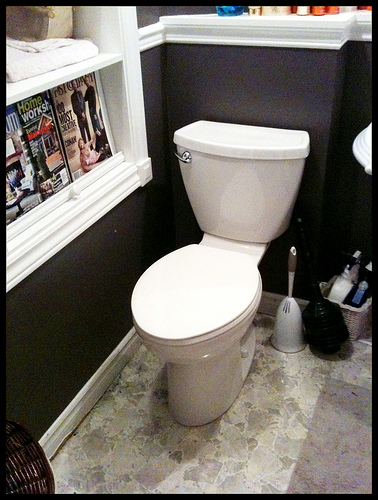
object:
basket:
[5, 420, 54, 494]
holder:
[268, 248, 307, 354]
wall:
[4, 4, 166, 470]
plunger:
[290, 210, 349, 357]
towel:
[5, 37, 98, 82]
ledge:
[157, 12, 352, 51]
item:
[213, 4, 242, 16]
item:
[246, 5, 261, 17]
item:
[295, 5, 310, 14]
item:
[275, 4, 291, 17]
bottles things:
[311, 6, 325, 19]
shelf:
[158, 11, 355, 50]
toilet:
[129, 118, 309, 430]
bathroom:
[5, 5, 373, 492]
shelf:
[5, 49, 121, 109]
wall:
[157, 1, 370, 333]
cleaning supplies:
[326, 258, 359, 307]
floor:
[49, 296, 372, 498]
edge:
[5, 419, 55, 496]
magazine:
[46, 69, 115, 184]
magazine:
[14, 89, 72, 202]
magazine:
[5, 108, 44, 228]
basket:
[318, 274, 373, 340]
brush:
[270, 245, 308, 355]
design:
[262, 390, 311, 442]